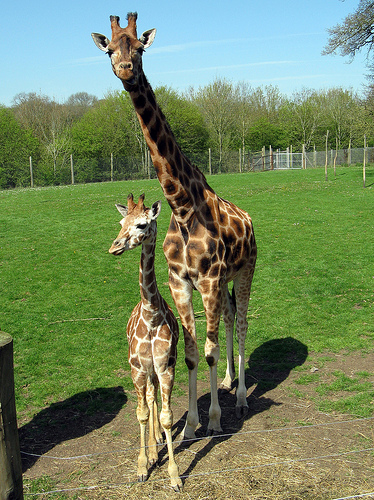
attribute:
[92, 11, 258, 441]
giraffe — tall, spotted, brown, tan, alert, penned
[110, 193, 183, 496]
giraffe — baby, standing, penned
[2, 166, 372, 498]
grass — short, green, brown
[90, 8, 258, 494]
giraffes — together, fenced in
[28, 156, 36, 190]
post — wooden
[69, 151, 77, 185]
post — wooden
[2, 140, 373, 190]
fence — modest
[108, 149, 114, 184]
post — wooden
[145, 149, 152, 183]
post — wooden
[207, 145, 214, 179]
post — wooden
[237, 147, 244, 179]
post — wooden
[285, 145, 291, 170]
post — wooden